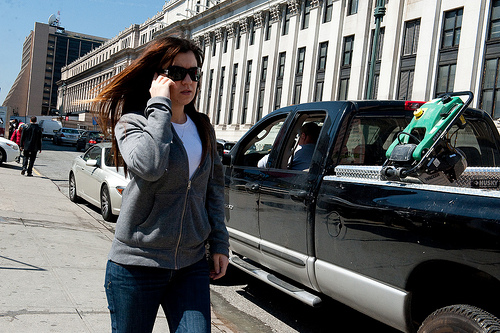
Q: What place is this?
A: It is a road.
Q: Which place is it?
A: It is a road.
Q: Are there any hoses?
A: No, there are no hoses.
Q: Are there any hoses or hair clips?
A: No, there are no hoses or hair clips.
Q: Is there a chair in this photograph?
A: No, there are no chairs.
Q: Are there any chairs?
A: No, there are no chairs.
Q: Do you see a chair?
A: No, there are no chairs.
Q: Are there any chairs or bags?
A: No, there are no chairs or bags.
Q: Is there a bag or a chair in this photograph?
A: No, there are no chairs or bags.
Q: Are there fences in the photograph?
A: No, there are no fences.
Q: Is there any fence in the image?
A: No, there are no fences.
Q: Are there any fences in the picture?
A: No, there are no fences.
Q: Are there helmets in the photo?
A: No, there are no helmets.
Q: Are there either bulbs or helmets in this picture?
A: No, there are no helmets or bulbs.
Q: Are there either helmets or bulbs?
A: No, there are no helmets or bulbs.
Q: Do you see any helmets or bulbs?
A: No, there are no helmets or bulbs.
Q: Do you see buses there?
A: No, there are no buses.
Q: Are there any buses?
A: No, there are no buses.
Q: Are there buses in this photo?
A: No, there are no buses.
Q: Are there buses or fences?
A: No, there are no buses or fences.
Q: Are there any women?
A: Yes, there is a woman.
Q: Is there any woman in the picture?
A: Yes, there is a woman.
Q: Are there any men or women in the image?
A: Yes, there is a woman.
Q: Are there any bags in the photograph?
A: No, there are no bags.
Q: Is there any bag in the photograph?
A: No, there are no bags.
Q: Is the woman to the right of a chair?
A: No, the woman is to the right of the car.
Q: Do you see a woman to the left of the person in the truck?
A: Yes, there is a woman to the left of the person.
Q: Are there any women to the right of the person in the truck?
A: No, the woman is to the left of the person.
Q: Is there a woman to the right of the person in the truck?
A: No, the woman is to the left of the person.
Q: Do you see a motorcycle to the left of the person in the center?
A: No, there is a woman to the left of the person.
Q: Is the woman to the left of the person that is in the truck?
A: Yes, the woman is to the left of the person.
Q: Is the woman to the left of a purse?
A: No, the woman is to the left of the person.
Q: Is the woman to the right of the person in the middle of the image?
A: No, the woman is to the left of the person.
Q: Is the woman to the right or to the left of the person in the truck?
A: The woman is to the left of the person.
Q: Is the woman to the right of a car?
A: Yes, the woman is to the right of a car.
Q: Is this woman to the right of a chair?
A: No, the woman is to the right of a car.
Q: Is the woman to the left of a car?
A: No, the woman is to the right of a car.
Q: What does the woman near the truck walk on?
A: The woman walks on the floor.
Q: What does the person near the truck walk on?
A: The woman walks on the floor.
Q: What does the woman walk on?
A: The woman walks on the floor.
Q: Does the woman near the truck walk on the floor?
A: Yes, the woman walks on the floor.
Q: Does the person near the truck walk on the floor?
A: Yes, the woman walks on the floor.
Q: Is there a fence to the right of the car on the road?
A: No, there is a woman to the right of the car.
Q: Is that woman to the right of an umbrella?
A: No, the woman is to the right of the car.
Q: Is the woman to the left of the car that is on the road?
A: No, the woman is to the right of the car.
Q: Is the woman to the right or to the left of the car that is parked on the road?
A: The woman is to the right of the car.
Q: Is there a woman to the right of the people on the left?
A: Yes, there is a woman to the right of the people.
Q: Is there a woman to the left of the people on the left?
A: No, the woman is to the right of the people.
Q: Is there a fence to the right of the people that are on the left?
A: No, there is a woman to the right of the people.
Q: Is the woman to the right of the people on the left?
A: Yes, the woman is to the right of the people.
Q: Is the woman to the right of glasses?
A: No, the woman is to the right of the people.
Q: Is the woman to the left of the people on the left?
A: No, the woman is to the right of the people.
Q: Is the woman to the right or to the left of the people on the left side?
A: The woman is to the right of the people.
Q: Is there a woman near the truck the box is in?
A: Yes, there is a woman near the truck.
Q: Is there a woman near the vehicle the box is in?
A: Yes, there is a woman near the truck.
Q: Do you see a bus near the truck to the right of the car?
A: No, there is a woman near the truck.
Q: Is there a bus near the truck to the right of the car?
A: No, there is a woman near the truck.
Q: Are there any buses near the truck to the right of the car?
A: No, there is a woman near the truck.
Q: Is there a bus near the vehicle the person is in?
A: No, there is a woman near the truck.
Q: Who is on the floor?
A: The woman is on the floor.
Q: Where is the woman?
A: The woman is on the floor.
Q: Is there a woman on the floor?
A: Yes, there is a woman on the floor.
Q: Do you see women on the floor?
A: Yes, there is a woman on the floor.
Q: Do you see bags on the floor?
A: No, there is a woman on the floor.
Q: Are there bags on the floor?
A: No, there is a woman on the floor.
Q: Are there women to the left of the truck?
A: Yes, there is a woman to the left of the truck.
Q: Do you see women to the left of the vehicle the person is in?
A: Yes, there is a woman to the left of the truck.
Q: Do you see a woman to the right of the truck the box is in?
A: No, the woman is to the left of the truck.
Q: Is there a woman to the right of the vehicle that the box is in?
A: No, the woman is to the left of the truck.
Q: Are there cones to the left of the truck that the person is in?
A: No, there is a woman to the left of the truck.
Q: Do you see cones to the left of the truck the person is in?
A: No, there is a woman to the left of the truck.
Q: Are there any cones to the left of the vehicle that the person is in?
A: No, there is a woman to the left of the truck.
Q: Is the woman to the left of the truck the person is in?
A: Yes, the woman is to the left of the truck.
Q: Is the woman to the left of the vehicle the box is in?
A: Yes, the woman is to the left of the truck.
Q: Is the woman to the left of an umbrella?
A: No, the woman is to the left of the truck.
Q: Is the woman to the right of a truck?
A: No, the woman is to the left of a truck.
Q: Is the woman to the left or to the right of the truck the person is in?
A: The woman is to the left of the truck.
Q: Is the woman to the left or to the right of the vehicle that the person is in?
A: The woman is to the left of the truck.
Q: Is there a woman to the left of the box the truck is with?
A: Yes, there is a woman to the left of the box.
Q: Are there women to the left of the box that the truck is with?
A: Yes, there is a woman to the left of the box.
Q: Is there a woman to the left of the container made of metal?
A: Yes, there is a woman to the left of the box.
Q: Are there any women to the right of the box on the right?
A: No, the woman is to the left of the box.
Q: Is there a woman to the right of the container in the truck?
A: No, the woman is to the left of the box.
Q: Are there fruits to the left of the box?
A: No, there is a woman to the left of the box.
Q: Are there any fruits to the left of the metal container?
A: No, there is a woman to the left of the box.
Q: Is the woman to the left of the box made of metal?
A: Yes, the woman is to the left of the box.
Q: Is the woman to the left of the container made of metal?
A: Yes, the woman is to the left of the box.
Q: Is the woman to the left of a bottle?
A: No, the woman is to the left of the box.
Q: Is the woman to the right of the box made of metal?
A: No, the woman is to the left of the box.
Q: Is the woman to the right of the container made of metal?
A: No, the woman is to the left of the box.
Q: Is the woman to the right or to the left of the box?
A: The woman is to the left of the box.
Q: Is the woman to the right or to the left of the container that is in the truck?
A: The woman is to the left of the box.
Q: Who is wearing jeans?
A: The woman is wearing jeans.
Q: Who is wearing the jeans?
A: The woman is wearing jeans.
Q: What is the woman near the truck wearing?
A: The woman is wearing jeans.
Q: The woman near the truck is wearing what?
A: The woman is wearing jeans.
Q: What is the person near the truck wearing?
A: The woman is wearing jeans.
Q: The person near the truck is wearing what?
A: The woman is wearing jeans.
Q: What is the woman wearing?
A: The woman is wearing jeans.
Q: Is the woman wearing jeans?
A: Yes, the woman is wearing jeans.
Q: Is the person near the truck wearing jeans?
A: Yes, the woman is wearing jeans.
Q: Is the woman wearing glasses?
A: No, the woman is wearing jeans.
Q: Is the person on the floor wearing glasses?
A: No, the woman is wearing jeans.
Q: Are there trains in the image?
A: No, there are no trains.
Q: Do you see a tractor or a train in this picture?
A: No, there are no trains or tractors.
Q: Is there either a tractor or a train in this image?
A: No, there are no trains or tractors.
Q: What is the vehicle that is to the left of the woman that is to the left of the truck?
A: The vehicle is a car.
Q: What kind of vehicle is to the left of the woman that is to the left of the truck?
A: The vehicle is a car.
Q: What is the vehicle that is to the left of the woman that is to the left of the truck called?
A: The vehicle is a car.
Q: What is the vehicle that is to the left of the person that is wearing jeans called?
A: The vehicle is a car.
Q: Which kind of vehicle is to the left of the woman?
A: The vehicle is a car.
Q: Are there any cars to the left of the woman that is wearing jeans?
A: Yes, there is a car to the left of the woman.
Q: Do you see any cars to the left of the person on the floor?
A: Yes, there is a car to the left of the woman.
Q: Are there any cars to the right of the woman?
A: No, the car is to the left of the woman.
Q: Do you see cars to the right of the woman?
A: No, the car is to the left of the woman.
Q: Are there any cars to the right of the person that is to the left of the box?
A: No, the car is to the left of the woman.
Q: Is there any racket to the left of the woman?
A: No, there is a car to the left of the woman.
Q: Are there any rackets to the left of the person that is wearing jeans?
A: No, there is a car to the left of the woman.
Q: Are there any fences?
A: No, there are no fences.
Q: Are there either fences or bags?
A: No, there are no fences or bags.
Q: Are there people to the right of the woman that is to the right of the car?
A: Yes, there is a person to the right of the woman.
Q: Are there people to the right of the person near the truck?
A: Yes, there is a person to the right of the woman.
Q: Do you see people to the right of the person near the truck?
A: Yes, there is a person to the right of the woman.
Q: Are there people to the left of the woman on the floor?
A: No, the person is to the right of the woman.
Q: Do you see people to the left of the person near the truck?
A: No, the person is to the right of the woman.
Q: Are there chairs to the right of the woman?
A: No, there is a person to the right of the woman.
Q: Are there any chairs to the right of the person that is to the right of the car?
A: No, there is a person to the right of the woman.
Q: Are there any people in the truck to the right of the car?
A: Yes, there is a person in the truck.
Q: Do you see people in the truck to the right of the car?
A: Yes, there is a person in the truck.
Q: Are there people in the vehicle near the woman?
A: Yes, there is a person in the truck.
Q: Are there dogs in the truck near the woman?
A: No, there is a person in the truck.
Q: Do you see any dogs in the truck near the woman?
A: No, there is a person in the truck.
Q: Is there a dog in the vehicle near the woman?
A: No, there is a person in the truck.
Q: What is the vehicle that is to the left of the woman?
A: The vehicle is a car.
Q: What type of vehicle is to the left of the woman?
A: The vehicle is a car.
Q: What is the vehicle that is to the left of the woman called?
A: The vehicle is a car.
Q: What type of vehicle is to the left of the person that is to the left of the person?
A: The vehicle is a car.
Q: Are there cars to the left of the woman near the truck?
A: Yes, there is a car to the left of the woman.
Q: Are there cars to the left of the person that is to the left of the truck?
A: Yes, there is a car to the left of the woman.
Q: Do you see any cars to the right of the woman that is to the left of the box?
A: No, the car is to the left of the woman.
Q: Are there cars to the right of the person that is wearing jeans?
A: No, the car is to the left of the woman.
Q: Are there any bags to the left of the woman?
A: No, there is a car to the left of the woman.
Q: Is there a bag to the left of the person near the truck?
A: No, there is a car to the left of the woman.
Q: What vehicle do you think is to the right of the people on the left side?
A: The vehicle is a car.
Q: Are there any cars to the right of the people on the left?
A: Yes, there is a car to the right of the people.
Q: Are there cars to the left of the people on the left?
A: No, the car is to the right of the people.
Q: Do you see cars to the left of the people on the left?
A: No, the car is to the right of the people.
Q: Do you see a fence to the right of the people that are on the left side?
A: No, there is a car to the right of the people.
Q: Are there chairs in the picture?
A: No, there are no chairs.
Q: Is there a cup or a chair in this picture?
A: No, there are no chairs or cups.